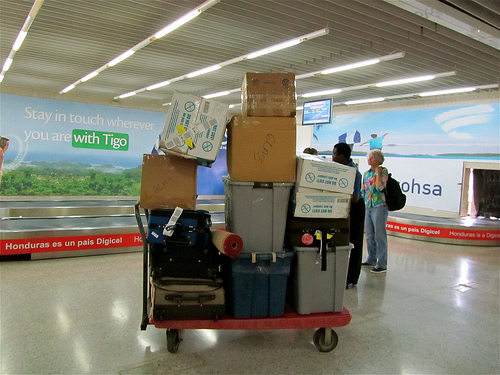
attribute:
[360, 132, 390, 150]
boy — a painting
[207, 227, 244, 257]
mat — tan, red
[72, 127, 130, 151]
box — green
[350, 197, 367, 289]
pants — dark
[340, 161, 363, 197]
shirt — blue, polo shirt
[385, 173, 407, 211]
backpack — black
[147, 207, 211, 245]
suitcase — blue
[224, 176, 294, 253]
bin — plastic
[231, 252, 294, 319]
bin — plastic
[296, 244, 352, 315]
bin — plastic